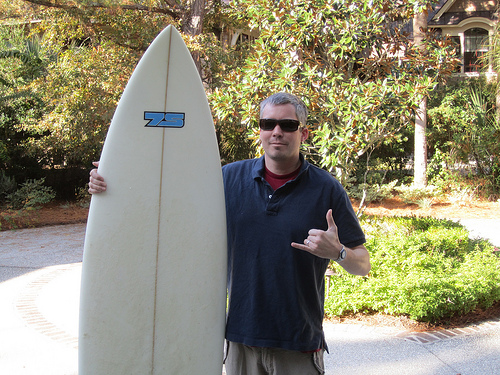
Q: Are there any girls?
A: No, there are no girls.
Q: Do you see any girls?
A: No, there are no girls.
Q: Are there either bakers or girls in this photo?
A: No, there are no girls or bakers.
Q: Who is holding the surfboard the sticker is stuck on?
A: The man is holding the surfboard.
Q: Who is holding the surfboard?
A: The man is holding the surfboard.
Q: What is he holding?
A: The man is holding the surfboard.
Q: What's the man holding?
A: The man is holding the surfboard.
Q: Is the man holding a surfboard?
A: Yes, the man is holding a surfboard.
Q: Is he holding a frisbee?
A: No, the man is holding a surfboard.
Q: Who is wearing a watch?
A: The man is wearing a watch.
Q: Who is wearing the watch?
A: The man is wearing a watch.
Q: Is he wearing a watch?
A: Yes, the man is wearing a watch.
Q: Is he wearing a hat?
A: No, the man is wearing a watch.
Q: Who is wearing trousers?
A: The man is wearing trousers.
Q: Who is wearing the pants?
A: The man is wearing trousers.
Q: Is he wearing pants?
A: Yes, the man is wearing pants.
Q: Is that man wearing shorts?
A: No, the man is wearing pants.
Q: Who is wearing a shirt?
A: The man is wearing a shirt.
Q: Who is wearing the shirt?
A: The man is wearing a shirt.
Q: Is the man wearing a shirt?
A: Yes, the man is wearing a shirt.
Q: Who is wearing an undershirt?
A: The man is wearing an undershirt.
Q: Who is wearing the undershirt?
A: The man is wearing an undershirt.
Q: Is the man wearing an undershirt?
A: Yes, the man is wearing an undershirt.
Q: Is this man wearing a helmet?
A: No, the man is wearing an undershirt.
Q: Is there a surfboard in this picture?
A: Yes, there is a surfboard.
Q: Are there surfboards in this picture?
A: Yes, there is a surfboard.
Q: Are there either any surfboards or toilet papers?
A: Yes, there is a surfboard.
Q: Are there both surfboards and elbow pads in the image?
A: No, there is a surfboard but no elbow pads.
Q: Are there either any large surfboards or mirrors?
A: Yes, there is a large surfboard.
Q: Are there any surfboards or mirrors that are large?
A: Yes, the surfboard is large.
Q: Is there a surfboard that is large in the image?
A: Yes, there is a large surfboard.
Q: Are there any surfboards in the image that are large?
A: Yes, there is a surfboard that is large.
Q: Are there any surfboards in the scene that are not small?
A: Yes, there is a large surfboard.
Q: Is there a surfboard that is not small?
A: Yes, there is a large surfboard.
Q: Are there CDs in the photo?
A: No, there are no cds.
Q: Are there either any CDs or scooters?
A: No, there are no CDs or scooters.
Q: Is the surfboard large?
A: Yes, the surfboard is large.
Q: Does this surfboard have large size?
A: Yes, the surfboard is large.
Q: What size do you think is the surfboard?
A: The surfboard is large.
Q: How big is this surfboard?
A: The surfboard is large.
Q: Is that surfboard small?
A: No, the surfboard is large.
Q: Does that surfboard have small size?
A: No, the surfboard is large.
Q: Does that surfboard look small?
A: No, the surfboard is large.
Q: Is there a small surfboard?
A: No, there is a surfboard but it is large.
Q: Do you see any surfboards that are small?
A: No, there is a surfboard but it is large.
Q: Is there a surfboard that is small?
A: No, there is a surfboard but it is large.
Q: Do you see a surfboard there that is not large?
A: No, there is a surfboard but it is large.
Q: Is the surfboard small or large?
A: The surfboard is large.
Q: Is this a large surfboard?
A: Yes, this is a large surfboard.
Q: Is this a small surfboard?
A: No, this is a large surfboard.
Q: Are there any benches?
A: No, there are no benches.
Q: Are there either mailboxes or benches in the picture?
A: No, there are no benches or mailboxes.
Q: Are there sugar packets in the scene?
A: No, there are no sugar packets.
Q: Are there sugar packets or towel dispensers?
A: No, there are no sugar packets or towel dispensers.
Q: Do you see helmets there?
A: No, there are no helmets.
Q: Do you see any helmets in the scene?
A: No, there are no helmets.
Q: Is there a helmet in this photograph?
A: No, there are no helmets.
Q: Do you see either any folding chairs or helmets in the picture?
A: No, there are no helmets or folding chairs.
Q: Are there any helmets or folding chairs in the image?
A: No, there are no helmets or folding chairs.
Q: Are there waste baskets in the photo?
A: No, there are no waste baskets.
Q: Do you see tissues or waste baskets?
A: No, there are no waste baskets or tissues.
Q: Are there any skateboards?
A: No, there are no skateboards.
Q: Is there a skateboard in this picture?
A: No, there are no skateboards.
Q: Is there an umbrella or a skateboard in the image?
A: No, there are no skateboards or umbrellas.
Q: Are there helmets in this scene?
A: No, there are no helmets.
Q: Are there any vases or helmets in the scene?
A: No, there are no helmets or vases.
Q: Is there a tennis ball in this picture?
A: No, there are no tennis balls.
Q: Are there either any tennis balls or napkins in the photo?
A: No, there are no tennis balls or napkins.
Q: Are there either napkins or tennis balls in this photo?
A: No, there are no tennis balls or napkins.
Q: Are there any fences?
A: No, there are no fences.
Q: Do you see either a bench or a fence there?
A: No, there are no fences or benches.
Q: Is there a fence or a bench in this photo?
A: No, there are no fences or benches.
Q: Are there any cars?
A: No, there are no cars.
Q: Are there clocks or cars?
A: No, there are no cars or clocks.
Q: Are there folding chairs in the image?
A: No, there are no folding chairs.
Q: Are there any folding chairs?
A: No, there are no folding chairs.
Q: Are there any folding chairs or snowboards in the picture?
A: No, there are no folding chairs or snowboards.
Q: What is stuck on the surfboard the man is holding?
A: The sticker is stuck on the surf board.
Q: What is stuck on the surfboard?
A: The sticker is stuck on the surf board.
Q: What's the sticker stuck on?
A: The sticker is stuck on the surfboard.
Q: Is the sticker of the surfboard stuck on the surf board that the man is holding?
A: Yes, the sticker is stuck on the surf board.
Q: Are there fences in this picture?
A: No, there are no fences.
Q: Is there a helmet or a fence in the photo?
A: No, there are no fences or helmets.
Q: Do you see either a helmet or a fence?
A: No, there are no fences or helmets.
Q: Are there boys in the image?
A: No, there are no boys.